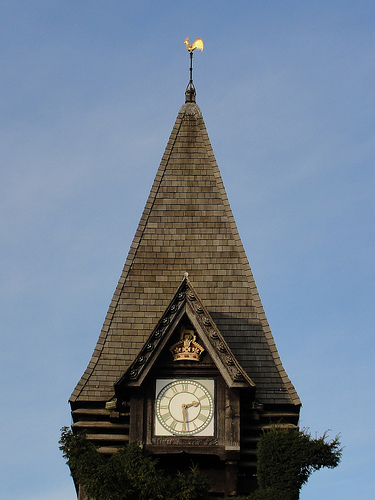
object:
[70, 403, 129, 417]
ridge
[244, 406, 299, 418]
ridge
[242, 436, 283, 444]
ridge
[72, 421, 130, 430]
ridge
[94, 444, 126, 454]
ridge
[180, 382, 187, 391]
roman numeral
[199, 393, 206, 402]
roman numeral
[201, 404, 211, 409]
roman numeral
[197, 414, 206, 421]
roman numeral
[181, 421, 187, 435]
roman numeral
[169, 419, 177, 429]
roman numeral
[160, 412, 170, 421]
roman numeral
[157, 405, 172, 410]
roman numeral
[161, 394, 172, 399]
roman numeral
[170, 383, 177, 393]
roman numeral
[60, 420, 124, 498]
trees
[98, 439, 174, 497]
trees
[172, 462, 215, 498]
trees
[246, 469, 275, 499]
trees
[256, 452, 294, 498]
trees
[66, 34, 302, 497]
building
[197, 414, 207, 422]
numeral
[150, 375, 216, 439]
clock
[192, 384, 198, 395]
roman numeral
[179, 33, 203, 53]
weather van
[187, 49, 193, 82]
pole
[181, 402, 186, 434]
clock hand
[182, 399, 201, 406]
clock hand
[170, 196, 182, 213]
bricks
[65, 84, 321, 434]
roof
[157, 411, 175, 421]
roman numeral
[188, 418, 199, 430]
roman numeral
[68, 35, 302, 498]
tower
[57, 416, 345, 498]
bush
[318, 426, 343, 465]
leaves